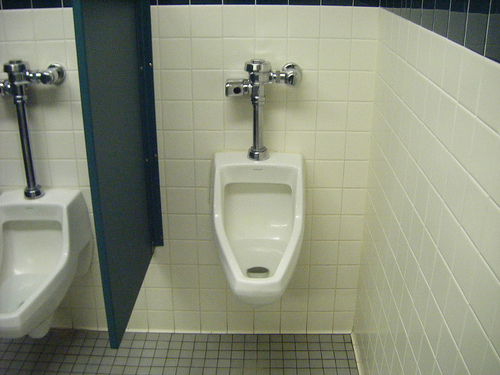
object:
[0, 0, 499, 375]
bathroom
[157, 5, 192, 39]
tile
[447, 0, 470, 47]
tile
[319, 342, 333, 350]
tile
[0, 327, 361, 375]
floor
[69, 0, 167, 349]
divider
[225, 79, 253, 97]
flushing apparatus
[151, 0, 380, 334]
wall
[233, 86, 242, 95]
motion censor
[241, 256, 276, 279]
water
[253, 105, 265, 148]
water pipe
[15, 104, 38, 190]
water pipe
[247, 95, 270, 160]
pipes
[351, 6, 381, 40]
tiles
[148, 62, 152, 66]
screws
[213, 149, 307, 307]
toilet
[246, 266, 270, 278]
hole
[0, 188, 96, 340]
toilet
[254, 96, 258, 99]
light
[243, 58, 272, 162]
silver